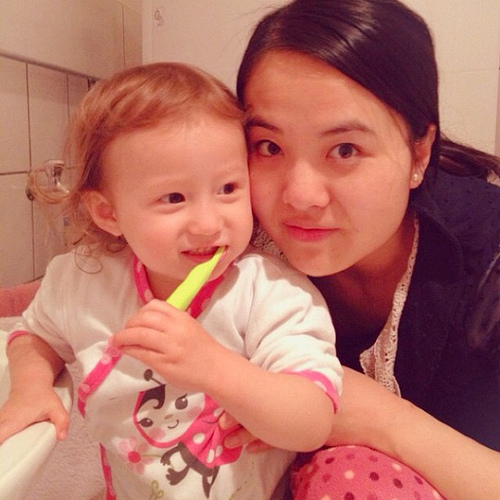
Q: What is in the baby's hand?
A: Toothbrush.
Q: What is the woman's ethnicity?
A: Asian.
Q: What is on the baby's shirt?
A: A ladybug.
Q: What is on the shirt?
A: The ladybug picture.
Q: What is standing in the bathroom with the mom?
A: The little girl.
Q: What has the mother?
A: The little girl.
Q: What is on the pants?
A: The polka dots.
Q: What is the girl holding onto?
A: The edge of the sink.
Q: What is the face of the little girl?
A: Happy.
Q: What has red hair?
A: The toddler.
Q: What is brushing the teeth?
A: The toddler.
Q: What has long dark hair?
A: The lady.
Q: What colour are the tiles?
A: White.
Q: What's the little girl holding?
A: Toothbrush.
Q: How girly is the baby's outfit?
A: Very girly.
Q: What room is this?
A: Bathroom.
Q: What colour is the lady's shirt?
A: Purple.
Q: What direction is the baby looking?
A: Right.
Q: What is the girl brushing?
A: Teeth.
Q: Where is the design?
A: On shirt.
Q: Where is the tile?
A: On wall.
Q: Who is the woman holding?
A: A child.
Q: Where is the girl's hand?
A: Bathtub rim.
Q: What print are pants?
A: Polka dots.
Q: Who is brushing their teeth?
A: A child.